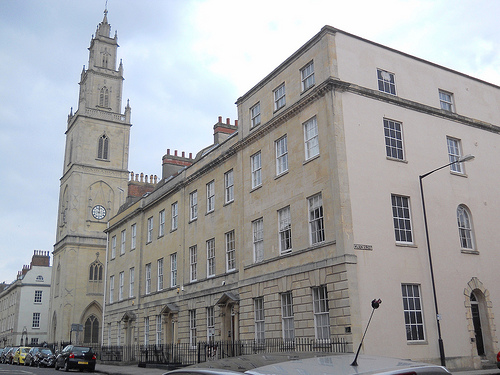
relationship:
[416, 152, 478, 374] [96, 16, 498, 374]
street light next to building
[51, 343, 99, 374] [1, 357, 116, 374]
vehicle on street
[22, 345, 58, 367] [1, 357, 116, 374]
vehicle on street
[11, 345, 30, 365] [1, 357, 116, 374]
vehicle on street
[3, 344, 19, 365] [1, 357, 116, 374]
vehicle on street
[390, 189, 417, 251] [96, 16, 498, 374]
window in building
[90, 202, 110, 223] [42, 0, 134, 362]
clock in tower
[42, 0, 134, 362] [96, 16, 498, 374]
tower next to building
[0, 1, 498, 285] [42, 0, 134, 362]
sky behind tower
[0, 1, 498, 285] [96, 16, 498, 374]
sky behind building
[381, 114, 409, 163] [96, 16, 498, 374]
window in building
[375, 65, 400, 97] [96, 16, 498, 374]
window in building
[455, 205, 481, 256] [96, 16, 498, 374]
window in building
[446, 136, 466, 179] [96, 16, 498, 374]
window in building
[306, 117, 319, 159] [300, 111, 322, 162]
curtains in window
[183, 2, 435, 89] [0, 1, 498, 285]
cloud in sky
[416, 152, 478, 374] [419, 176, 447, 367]
street light has post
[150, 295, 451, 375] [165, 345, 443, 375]
car has roof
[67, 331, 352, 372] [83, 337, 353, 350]
fence has top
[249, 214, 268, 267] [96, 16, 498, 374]
window in building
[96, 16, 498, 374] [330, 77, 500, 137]
building has edge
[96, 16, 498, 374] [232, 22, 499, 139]
building has top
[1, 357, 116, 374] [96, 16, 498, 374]
road next to building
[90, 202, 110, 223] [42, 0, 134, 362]
clock on tower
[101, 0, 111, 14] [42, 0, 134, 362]
cross on tower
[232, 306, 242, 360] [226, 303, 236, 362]
pillar next to doorway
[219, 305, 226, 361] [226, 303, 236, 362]
pillar next to doorway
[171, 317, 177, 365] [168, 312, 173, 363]
pillar next to doorway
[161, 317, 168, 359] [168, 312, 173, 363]
pillar next to doorway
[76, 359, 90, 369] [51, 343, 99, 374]
license plate on car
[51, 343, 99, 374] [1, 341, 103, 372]
vehicle in row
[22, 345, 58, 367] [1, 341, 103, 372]
vehicle in row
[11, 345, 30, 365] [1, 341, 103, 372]
vehicle in row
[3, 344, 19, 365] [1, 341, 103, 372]
vehicle in row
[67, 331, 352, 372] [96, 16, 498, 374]
fence in front of building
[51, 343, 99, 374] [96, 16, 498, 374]
vehicle in front of building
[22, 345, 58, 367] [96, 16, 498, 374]
vehicle in front of building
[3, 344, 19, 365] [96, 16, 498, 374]
vehicle in front of building